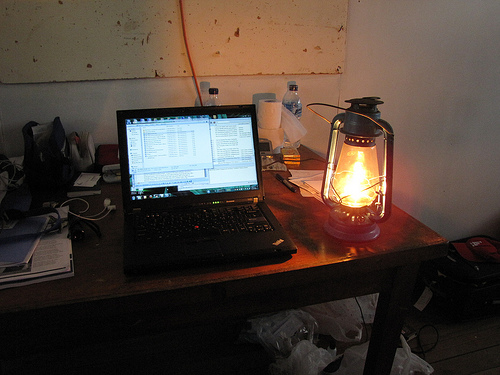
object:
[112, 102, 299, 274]
laptop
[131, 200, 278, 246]
keyboard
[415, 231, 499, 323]
luggage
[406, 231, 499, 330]
belongings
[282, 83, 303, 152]
water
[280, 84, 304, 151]
consumption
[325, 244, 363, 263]
brown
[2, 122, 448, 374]
desk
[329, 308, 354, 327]
white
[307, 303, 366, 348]
bag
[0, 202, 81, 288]
book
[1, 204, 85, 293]
learning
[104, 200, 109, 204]
white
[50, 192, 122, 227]
cord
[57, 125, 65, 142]
blue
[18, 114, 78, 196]
box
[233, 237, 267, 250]
black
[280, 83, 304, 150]
bottle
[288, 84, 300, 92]
top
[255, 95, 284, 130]
roll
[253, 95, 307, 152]
paper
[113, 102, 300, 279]
instrument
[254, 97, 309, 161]
rolls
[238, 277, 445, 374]
bags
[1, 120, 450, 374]
table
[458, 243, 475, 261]
red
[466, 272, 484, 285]
black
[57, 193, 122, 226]
pair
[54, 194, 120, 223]
earbuds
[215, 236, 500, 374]
floor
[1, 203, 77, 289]
stack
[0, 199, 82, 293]
paper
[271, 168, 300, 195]
pen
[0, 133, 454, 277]
wooden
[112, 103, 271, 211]
top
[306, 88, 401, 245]
latern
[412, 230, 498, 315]
bag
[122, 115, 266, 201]
screen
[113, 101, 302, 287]
computer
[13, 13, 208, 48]
white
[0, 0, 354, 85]
board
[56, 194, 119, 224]
cable